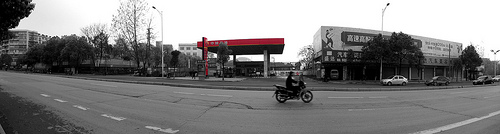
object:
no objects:
[458, 98, 489, 108]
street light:
[150, 6, 157, 10]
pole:
[161, 18, 167, 78]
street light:
[383, 2, 393, 7]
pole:
[378, 15, 386, 82]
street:
[0, 76, 500, 134]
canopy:
[195, 37, 288, 55]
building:
[234, 61, 298, 76]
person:
[285, 71, 297, 90]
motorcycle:
[271, 83, 316, 103]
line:
[39, 92, 52, 98]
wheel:
[275, 94, 290, 103]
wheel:
[299, 91, 314, 103]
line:
[96, 112, 129, 123]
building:
[0, 29, 48, 57]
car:
[380, 74, 411, 86]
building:
[308, 25, 480, 83]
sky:
[179, 1, 330, 27]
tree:
[216, 41, 233, 81]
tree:
[59, 38, 93, 75]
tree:
[19, 35, 63, 74]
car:
[423, 75, 452, 86]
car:
[472, 75, 497, 85]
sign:
[311, 25, 463, 57]